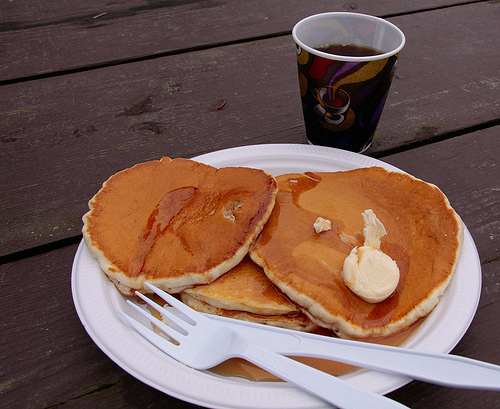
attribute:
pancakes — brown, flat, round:
[83, 157, 461, 340]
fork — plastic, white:
[117, 280, 409, 409]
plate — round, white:
[71, 142, 482, 409]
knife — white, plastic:
[156, 305, 499, 390]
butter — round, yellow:
[313, 209, 424, 303]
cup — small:
[291, 11, 408, 155]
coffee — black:
[313, 45, 384, 57]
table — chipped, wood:
[0, 1, 497, 407]